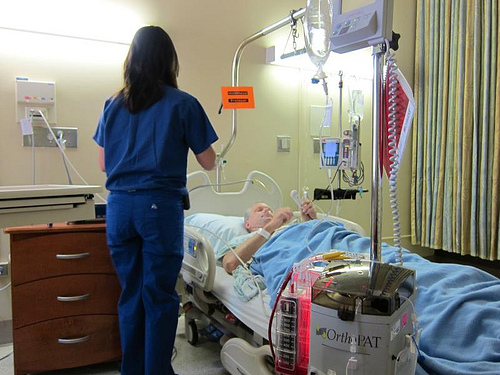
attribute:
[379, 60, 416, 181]
folder — red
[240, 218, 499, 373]
blanket — light blue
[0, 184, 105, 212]
tray — white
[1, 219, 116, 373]
cabinet — brown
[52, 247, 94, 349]
handles — metal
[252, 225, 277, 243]
bracelet — white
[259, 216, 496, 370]
blanket — blue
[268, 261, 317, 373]
machine — red, plastic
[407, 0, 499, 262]
curtains — yellow, blue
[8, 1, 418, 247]
wall — white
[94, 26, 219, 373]
lady — light skinned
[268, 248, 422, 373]
equipment — large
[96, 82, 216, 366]
scrub — blue